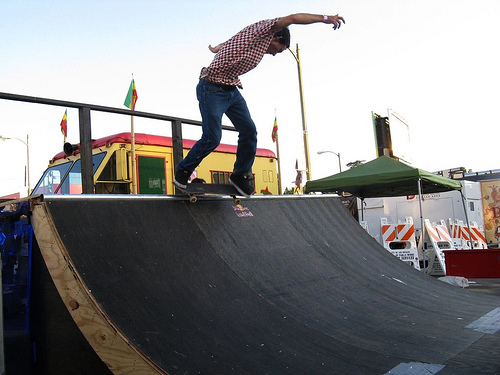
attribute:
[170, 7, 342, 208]
skateboarder —  blue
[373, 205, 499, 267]
signs — white, orange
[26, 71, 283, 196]
food truck — yellow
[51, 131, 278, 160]
top — red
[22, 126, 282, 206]
truck — red, yellow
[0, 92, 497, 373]
ramp — black, skate ramp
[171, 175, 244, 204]
skateboard — black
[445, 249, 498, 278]
fence — short, red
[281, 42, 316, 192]
light — tall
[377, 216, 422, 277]
barrier — safety barrier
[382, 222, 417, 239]
orange/white stripes — orange, white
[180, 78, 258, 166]
blue jeans —  skateboarder's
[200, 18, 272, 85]
shirt — red, plaid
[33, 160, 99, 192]
windows — large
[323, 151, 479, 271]
tent — small, green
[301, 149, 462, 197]
tent — green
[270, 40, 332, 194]
light pole — tall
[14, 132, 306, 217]
truck — yellow, red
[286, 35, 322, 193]
pole — long, electric